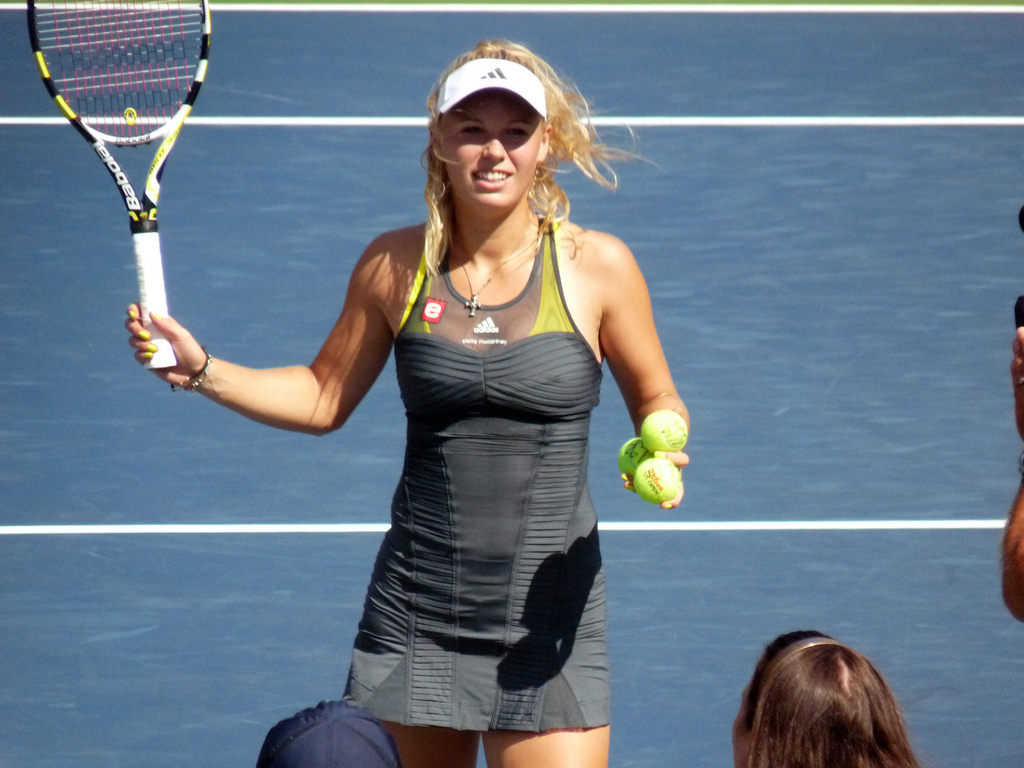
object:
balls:
[636, 406, 693, 454]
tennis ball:
[616, 432, 656, 481]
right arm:
[213, 240, 405, 464]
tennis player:
[117, 26, 697, 763]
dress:
[336, 216, 621, 744]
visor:
[414, 52, 545, 119]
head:
[728, 625, 923, 768]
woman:
[722, 627, 917, 761]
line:
[0, 518, 1005, 535]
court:
[0, 0, 1024, 767]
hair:
[410, 30, 631, 264]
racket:
[19, 5, 221, 369]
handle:
[124, 230, 176, 367]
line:
[0, 113, 1022, 130]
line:
[0, 5, 1022, 12]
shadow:
[488, 515, 614, 691]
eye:
[493, 119, 536, 145]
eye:
[454, 119, 490, 146]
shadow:
[425, 91, 540, 152]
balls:
[629, 455, 684, 503]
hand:
[603, 434, 701, 515]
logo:
[466, 56, 516, 86]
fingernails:
[135, 326, 154, 343]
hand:
[120, 302, 211, 389]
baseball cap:
[247, 692, 398, 765]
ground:
[0, 0, 1024, 768]